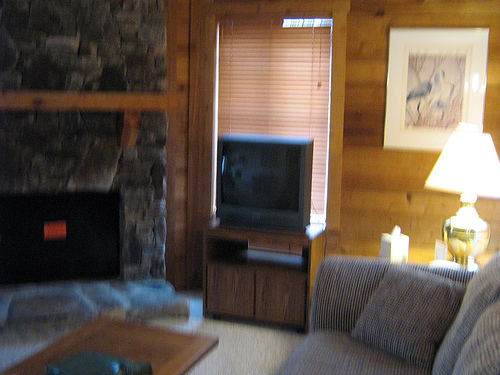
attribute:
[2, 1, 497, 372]
picture — blurry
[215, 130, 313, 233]
tv — analog, in room, large, grey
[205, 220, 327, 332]
stand — wood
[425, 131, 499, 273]
lamp — on, beige, white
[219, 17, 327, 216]
blinds — drawn, closed, brown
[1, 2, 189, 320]
fireplace — stone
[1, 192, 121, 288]
fire — not burning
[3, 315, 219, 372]
table — wooden, wood, coffee, brown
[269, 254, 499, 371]
couch — empty, grey, upholstered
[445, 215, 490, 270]
lamp base — gold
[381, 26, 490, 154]
picture — hanging, framed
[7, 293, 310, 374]
carpet — beige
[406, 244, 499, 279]
table — side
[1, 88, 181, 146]
shelf — wooden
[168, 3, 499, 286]
panelling — wood